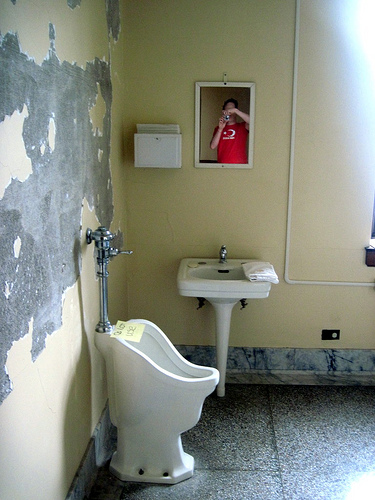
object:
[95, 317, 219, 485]
urinal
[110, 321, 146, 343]
sign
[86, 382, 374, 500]
floor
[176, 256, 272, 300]
sink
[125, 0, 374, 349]
wall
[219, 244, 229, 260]
faucet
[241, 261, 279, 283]
towel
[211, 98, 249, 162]
reflection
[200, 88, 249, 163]
mirror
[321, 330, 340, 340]
outlet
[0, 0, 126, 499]
wall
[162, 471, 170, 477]
bolt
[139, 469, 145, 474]
bolt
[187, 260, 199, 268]
soap bar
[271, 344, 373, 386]
baseboard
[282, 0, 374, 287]
water pipe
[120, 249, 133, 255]
handle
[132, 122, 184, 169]
paper towel holder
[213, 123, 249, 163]
shirt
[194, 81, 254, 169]
frame